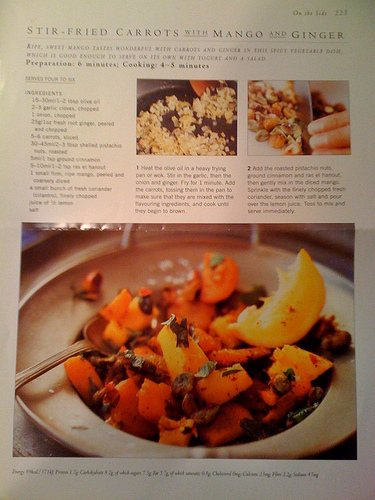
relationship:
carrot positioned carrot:
[201, 370, 250, 402] [205, 257, 239, 307]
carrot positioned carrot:
[104, 296, 139, 327] [205, 257, 239, 307]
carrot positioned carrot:
[56, 360, 105, 399] [205, 257, 239, 307]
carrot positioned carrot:
[142, 377, 167, 424] [205, 257, 239, 307]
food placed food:
[63, 354, 103, 401] [156, 318, 211, 382]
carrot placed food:
[99, 287, 151, 332] [156, 318, 211, 382]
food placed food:
[156, 417, 192, 444] [156, 318, 211, 382]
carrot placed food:
[200, 257, 239, 303] [156, 318, 211, 382]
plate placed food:
[16, 231, 354, 458] [156, 318, 211, 382]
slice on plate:
[230, 243, 324, 345] [16, 231, 354, 458]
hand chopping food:
[307, 106, 349, 154] [71, 245, 352, 446]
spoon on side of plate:
[13, 312, 114, 397] [16, 231, 354, 458]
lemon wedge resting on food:
[231, 246, 326, 349] [71, 245, 352, 446]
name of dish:
[26, 25, 345, 39] [24, 24, 348, 45]